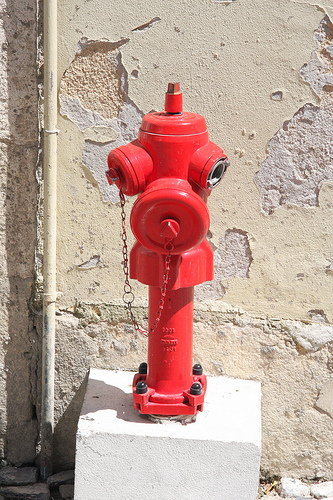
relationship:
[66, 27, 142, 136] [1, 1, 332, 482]
crack in wall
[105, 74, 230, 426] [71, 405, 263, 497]
hydrant on top of concrete block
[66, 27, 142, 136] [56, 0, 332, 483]
crack on wall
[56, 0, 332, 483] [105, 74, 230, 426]
wall behind hydrant